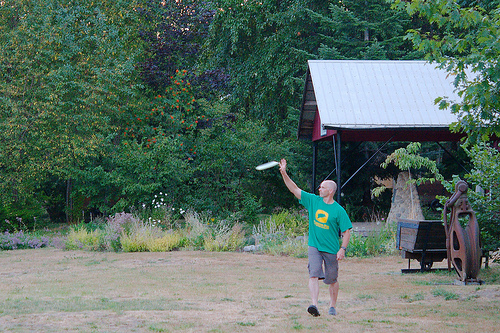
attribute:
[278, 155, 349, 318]
man — playing, bald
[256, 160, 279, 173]
frisbee — white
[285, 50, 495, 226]
barn — red, large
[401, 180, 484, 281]
equipment — old, rusted, decorative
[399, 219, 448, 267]
cart — wooden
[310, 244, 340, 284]
shorts — gray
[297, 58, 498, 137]
roof — white, metal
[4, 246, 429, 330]
grass — brown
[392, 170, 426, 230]
object — stone